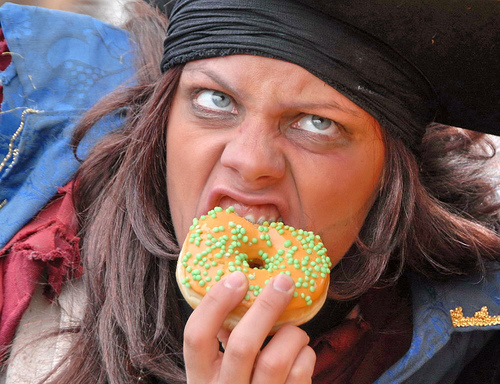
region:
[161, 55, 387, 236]
this is a woman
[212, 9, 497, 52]
this is a tavern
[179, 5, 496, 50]
the tavern is black in color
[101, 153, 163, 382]
the hair is brown in color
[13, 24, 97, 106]
the cloth is blue in color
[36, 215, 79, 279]
the cloth is red in color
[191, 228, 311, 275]
this is a doughnut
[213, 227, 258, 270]
the doughnut has some sprinkles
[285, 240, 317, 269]
the sprinkles are green in color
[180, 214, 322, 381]
the woman is holding the doughnut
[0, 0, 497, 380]
person eating donut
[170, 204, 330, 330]
round donut with brown frosting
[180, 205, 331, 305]
green sprinkles on top of donut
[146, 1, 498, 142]
woman wearing black cap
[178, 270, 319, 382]
hand holding donut near mouth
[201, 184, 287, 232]
mouth open to bite donut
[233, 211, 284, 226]
teeth showing in mouth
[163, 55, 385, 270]
woman's face scrunched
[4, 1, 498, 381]
long brown hair on woman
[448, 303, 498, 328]
gold design on collar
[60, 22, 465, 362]
a person enjoying a doughnut.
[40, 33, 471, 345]
person biting into a doughnut.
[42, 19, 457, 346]
person eating a delicious doughnut.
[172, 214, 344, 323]
a doughnut with green sprinkles.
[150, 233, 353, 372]
a hand holding a doughnut.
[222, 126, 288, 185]
nose of a person.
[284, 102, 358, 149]
left eye of a person.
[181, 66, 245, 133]
right eye of a person.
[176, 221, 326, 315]
two fingers and a doughnut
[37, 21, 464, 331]
a person with dark colored hair.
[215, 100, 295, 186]
woman's scrunched up nose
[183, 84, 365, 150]
eyes of the woman looking upward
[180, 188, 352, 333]
doughnut being eaten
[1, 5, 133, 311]
blue fabric in the background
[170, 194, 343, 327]
orange icing and green sprinkles on the doughnut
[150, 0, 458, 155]
black headdress wrapped around the head of the woman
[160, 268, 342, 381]
hand of the woman holding a doughnut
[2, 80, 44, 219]
white beads on the blue fabric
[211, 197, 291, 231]
teeth of the woman sinking into the doughnut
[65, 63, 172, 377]
hair of the woman hanging over her shoulder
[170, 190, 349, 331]
orange frosted donut with green sprinkles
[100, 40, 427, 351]
woman eating a donut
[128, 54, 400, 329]
angry orange faced woman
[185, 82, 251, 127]
woman's eye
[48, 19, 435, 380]
woman with brown hair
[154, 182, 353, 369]
arched lips eating a donut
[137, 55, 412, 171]
womans eyebrows on orange paint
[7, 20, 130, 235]
blue fabric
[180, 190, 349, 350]
round donut with frosting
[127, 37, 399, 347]
donut being devoured by angry woman